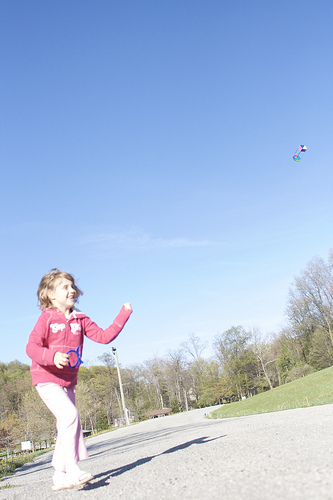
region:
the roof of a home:
[138, 407, 173, 412]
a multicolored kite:
[287, 141, 308, 160]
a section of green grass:
[205, 364, 332, 422]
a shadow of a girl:
[74, 427, 229, 493]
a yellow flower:
[2, 459, 8, 467]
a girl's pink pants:
[38, 377, 90, 466]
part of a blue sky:
[1, 0, 200, 135]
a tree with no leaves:
[181, 336, 210, 362]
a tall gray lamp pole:
[106, 346, 132, 427]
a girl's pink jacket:
[24, 306, 130, 382]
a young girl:
[24, 266, 133, 490]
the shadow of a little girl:
[78, 434, 233, 491]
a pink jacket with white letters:
[25, 306, 133, 388]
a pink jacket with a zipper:
[25, 304, 134, 386]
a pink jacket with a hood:
[25, 306, 132, 387]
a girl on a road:
[24, 267, 131, 489]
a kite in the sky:
[291, 143, 307, 162]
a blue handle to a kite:
[65, 344, 84, 369]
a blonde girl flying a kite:
[24, 267, 131, 491]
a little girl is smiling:
[25, 267, 133, 492]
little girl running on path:
[18, 252, 121, 495]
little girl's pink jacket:
[23, 306, 136, 383]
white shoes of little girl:
[46, 463, 97, 491]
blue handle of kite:
[64, 347, 81, 368]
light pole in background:
[109, 344, 135, 432]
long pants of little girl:
[39, 383, 87, 466]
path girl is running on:
[34, 411, 332, 488]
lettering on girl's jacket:
[48, 324, 82, 336]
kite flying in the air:
[288, 138, 309, 162]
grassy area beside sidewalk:
[214, 377, 328, 406]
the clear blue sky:
[8, 6, 154, 80]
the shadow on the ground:
[88, 421, 223, 486]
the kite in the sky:
[281, 138, 311, 167]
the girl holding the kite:
[22, 265, 147, 487]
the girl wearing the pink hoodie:
[30, 297, 130, 398]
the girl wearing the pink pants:
[13, 365, 97, 464]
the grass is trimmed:
[224, 379, 331, 416]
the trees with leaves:
[214, 334, 331, 382]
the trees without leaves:
[135, 351, 199, 397]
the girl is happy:
[29, 266, 89, 315]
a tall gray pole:
[109, 347, 126, 424]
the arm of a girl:
[79, 317, 126, 342]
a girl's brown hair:
[36, 266, 83, 313]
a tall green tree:
[217, 325, 259, 399]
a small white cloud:
[100, 226, 233, 252]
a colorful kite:
[288, 137, 310, 164]